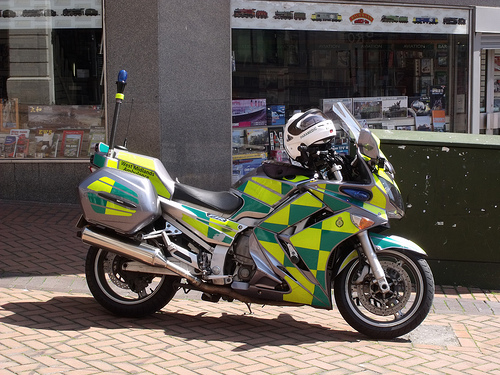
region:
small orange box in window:
[431, 109, 446, 131]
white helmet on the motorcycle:
[281, 106, 336, 161]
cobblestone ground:
[2, 201, 497, 373]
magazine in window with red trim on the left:
[60, 128, 84, 158]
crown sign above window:
[349, 8, 374, 27]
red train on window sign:
[233, 8, 268, 20]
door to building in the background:
[477, 34, 497, 135]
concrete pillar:
[102, 1, 234, 206]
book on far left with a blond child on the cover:
[1, 98, 18, 133]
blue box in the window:
[267, 104, 286, 125]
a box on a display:
[227, 92, 264, 129]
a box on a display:
[263, 105, 287, 122]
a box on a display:
[230, 120, 270, 158]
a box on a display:
[231, 150, 271, 186]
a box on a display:
[322, 95, 357, 135]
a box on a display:
[354, 93, 383, 118]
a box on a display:
[380, 92, 411, 114]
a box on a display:
[380, 117, 415, 131]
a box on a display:
[415, 109, 432, 133]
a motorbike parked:
[77, 47, 432, 349]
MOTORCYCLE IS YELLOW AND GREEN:
[48, 70, 498, 372]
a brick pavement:
[190, 333, 282, 368]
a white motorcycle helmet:
[279, 100, 339, 152]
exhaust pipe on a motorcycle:
[74, 223, 159, 265]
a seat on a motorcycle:
[174, 174, 239, 214]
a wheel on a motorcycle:
[334, 248, 444, 335]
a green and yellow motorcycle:
[240, 180, 403, 316]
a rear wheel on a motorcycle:
[80, 243, 182, 315]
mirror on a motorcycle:
[356, 130, 386, 157]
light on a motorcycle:
[85, 139, 121, 164]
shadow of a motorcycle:
[7, 287, 87, 341]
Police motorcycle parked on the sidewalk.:
[66, 49, 469, 353]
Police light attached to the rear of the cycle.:
[92, 61, 144, 158]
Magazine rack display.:
[1, 99, 111, 169]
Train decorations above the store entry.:
[232, 0, 470, 32]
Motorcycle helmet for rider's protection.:
[271, 97, 346, 168]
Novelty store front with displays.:
[233, 37, 497, 189]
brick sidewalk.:
[6, 288, 271, 371]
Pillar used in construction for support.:
[101, 2, 247, 307]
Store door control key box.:
[452, 89, 469, 117]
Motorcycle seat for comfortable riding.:
[168, 165, 263, 219]